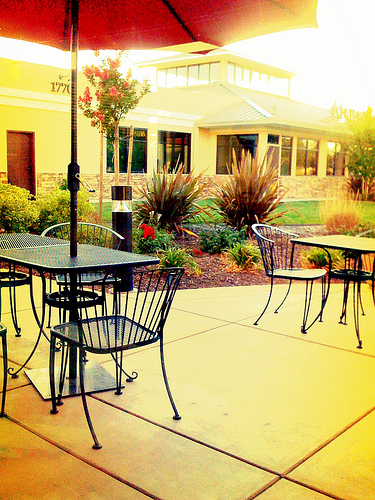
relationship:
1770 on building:
[50, 75, 70, 95] [0, 44, 360, 202]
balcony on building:
[139, 45, 309, 92] [38, 45, 370, 235]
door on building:
[6, 130, 38, 199] [0, 44, 360, 202]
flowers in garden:
[140, 220, 158, 240] [1, 159, 373, 285]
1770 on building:
[47, 76, 73, 96] [5, 48, 362, 215]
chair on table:
[225, 205, 327, 287] [288, 218, 372, 263]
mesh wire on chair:
[55, 314, 153, 348] [45, 265, 185, 451]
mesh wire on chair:
[57, 271, 115, 280] [37, 214, 124, 336]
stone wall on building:
[37, 173, 349, 200] [1, 58, 373, 199]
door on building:
[6, 130, 35, 196] [7, 46, 347, 232]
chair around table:
[45, 265, 185, 451] [24, 229, 152, 288]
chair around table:
[39, 220, 126, 330] [24, 229, 152, 288]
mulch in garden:
[106, 218, 331, 286] [1, 159, 373, 285]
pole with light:
[112, 183, 135, 291] [113, 195, 128, 212]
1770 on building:
[50, 75, 70, 95] [1, 58, 373, 199]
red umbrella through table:
[0, 0, 318, 52] [0, 241, 158, 288]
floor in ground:
[0, 264, 372, 500] [1, 268, 374, 497]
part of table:
[84, 245, 130, 274] [282, 205, 374, 305]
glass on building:
[296, 146, 317, 174] [0, 44, 360, 202]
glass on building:
[170, 133, 180, 160] [0, 44, 360, 202]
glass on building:
[218, 135, 256, 152] [0, 44, 360, 202]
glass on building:
[326, 140, 343, 174] [0, 44, 360, 202]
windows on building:
[151, 130, 194, 178] [0, 44, 360, 202]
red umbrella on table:
[0, 0, 318, 52] [0, 232, 160, 401]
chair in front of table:
[45, 265, 185, 451] [0, 232, 160, 401]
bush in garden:
[207, 142, 306, 240] [0, 143, 373, 292]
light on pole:
[110, 200, 133, 212] [110, 183, 134, 290]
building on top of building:
[0, 41, 375, 208] [1, 35, 366, 246]